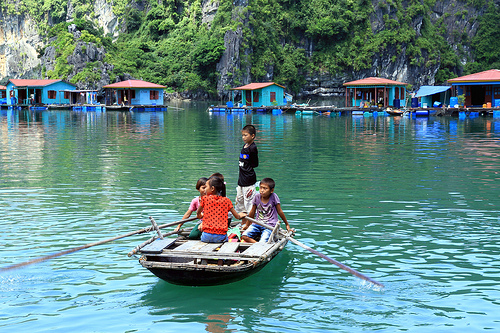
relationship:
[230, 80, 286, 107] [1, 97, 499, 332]
hut on river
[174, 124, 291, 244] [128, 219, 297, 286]
children riding on boat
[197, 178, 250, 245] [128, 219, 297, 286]
girl moving boat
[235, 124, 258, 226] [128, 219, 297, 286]
boy standing on boat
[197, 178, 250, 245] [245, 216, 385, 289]
girl using an oar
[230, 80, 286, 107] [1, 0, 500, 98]
hut in front of mountain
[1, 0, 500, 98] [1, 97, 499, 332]
mountain on river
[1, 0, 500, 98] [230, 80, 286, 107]
mountain behind hut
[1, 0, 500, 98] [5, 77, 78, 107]
mountain behind hut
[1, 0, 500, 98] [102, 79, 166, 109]
mountain behind hut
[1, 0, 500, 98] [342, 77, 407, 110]
mountain behind hut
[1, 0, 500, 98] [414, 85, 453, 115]
mountain behind hut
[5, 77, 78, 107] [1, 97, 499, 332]
hut on river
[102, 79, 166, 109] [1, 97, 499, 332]
hut on river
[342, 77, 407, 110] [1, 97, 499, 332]
hut on river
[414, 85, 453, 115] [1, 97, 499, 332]
hut on river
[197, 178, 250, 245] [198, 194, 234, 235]
girl wearing blouse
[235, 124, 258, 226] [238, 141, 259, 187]
boy in t-shirt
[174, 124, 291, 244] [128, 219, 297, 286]
children on boat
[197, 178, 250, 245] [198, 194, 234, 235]
girl in blouse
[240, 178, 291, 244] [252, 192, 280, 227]
boy in shirt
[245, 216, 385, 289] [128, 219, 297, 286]
oar for boat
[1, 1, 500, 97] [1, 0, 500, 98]
vegetation on mountain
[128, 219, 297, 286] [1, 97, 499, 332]
boat on river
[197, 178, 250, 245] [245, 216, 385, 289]
girl with an oar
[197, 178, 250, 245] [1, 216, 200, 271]
girl with oar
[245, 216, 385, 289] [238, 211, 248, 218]
an oar in hand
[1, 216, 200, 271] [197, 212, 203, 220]
oar in hand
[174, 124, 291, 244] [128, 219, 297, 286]
children paddling boat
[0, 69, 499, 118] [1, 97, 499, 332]
community on river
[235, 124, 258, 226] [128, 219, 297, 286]
boy standing in boat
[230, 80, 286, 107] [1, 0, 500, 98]
hut at bottom of mountain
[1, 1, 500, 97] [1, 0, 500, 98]
vegetation growing out of mountain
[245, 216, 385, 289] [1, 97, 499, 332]
an oar in river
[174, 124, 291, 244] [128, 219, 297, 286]
children in boat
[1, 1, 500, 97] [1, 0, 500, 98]
vegetation around mountain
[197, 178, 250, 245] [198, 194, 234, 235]
girl with blouse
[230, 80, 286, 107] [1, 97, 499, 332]
hut floating on river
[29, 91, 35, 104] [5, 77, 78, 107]
person outside hut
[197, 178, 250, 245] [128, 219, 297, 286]
girl rowing boat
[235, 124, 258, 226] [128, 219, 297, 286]
boy riding atop boat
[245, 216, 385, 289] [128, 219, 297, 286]
an oar used to steer boat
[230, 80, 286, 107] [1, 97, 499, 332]
hut at edge of river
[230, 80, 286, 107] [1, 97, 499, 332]
hut floating atop river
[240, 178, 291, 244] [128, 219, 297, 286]
boy sitting in boat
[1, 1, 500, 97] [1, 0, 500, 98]
vegetation adorning mountain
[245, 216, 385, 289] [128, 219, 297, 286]
an oar useful for steering boat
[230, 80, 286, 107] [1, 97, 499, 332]
hut set back from river